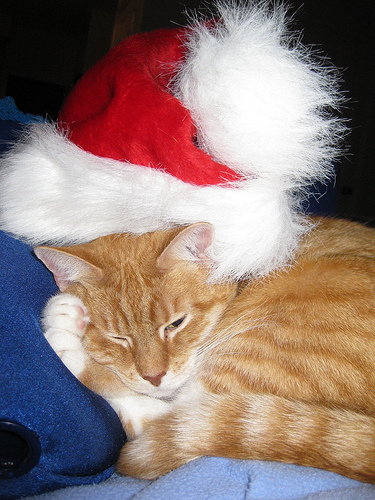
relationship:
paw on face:
[42, 327, 88, 370] [33, 221, 238, 396]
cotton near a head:
[161, 2, 356, 189] [29, 216, 226, 400]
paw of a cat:
[39, 296, 101, 385] [27, 210, 373, 496]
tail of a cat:
[125, 385, 372, 480] [27, 210, 373, 496]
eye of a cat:
[154, 311, 192, 335] [27, 210, 373, 496]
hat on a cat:
[0, 0, 351, 292] [27, 210, 373, 496]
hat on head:
[0, 0, 351, 292] [33, 220, 232, 335]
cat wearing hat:
[27, 210, 373, 496] [0, 0, 351, 292]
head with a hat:
[33, 220, 232, 335] [0, 0, 351, 292]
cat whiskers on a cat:
[180, 312, 269, 364] [27, 210, 373, 496]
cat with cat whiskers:
[27, 210, 373, 496] [180, 312, 269, 364]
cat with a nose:
[27, 210, 373, 496] [136, 357, 170, 386]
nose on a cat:
[136, 357, 170, 386] [27, 210, 373, 496]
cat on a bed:
[32, 210, 375, 486] [2, 231, 370, 500]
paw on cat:
[42, 327, 88, 370] [27, 210, 373, 496]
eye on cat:
[154, 311, 192, 335] [27, 210, 373, 496]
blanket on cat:
[182, 468, 282, 498] [27, 210, 373, 496]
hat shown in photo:
[3, 10, 359, 274] [2, 2, 363, 499]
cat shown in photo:
[27, 210, 373, 496] [2, 2, 363, 499]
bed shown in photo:
[2, 231, 370, 500] [2, 2, 363, 499]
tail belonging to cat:
[112, 385, 375, 490] [27, 210, 373, 496]